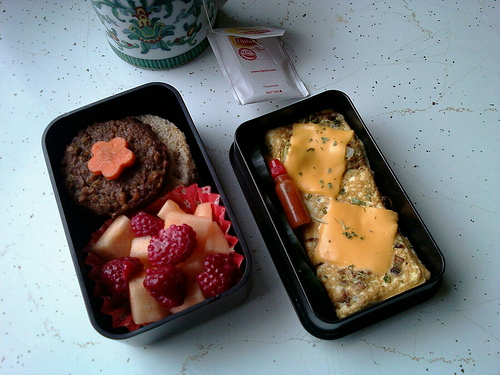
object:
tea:
[204, 21, 311, 106]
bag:
[204, 26, 311, 106]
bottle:
[268, 158, 313, 230]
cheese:
[283, 121, 399, 273]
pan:
[229, 89, 448, 340]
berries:
[146, 222, 198, 269]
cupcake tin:
[84, 182, 248, 333]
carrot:
[86, 136, 135, 181]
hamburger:
[61, 119, 169, 216]